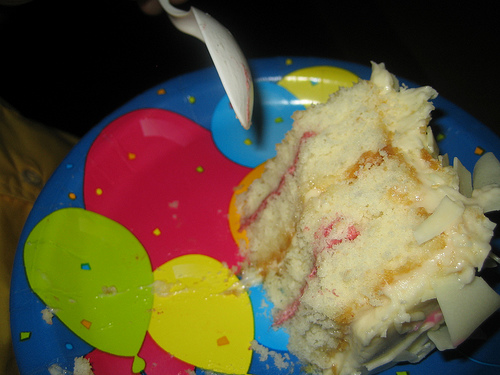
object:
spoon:
[158, 0, 255, 131]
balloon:
[24, 207, 153, 374]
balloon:
[147, 254, 254, 375]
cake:
[238, 60, 500, 374]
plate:
[9, 58, 500, 375]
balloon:
[211, 82, 305, 169]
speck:
[217, 336, 230, 346]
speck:
[20, 332, 31, 341]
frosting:
[232, 59, 495, 374]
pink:
[83, 107, 252, 274]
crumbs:
[41, 308, 297, 375]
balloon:
[84, 109, 256, 276]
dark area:
[1, 1, 500, 141]